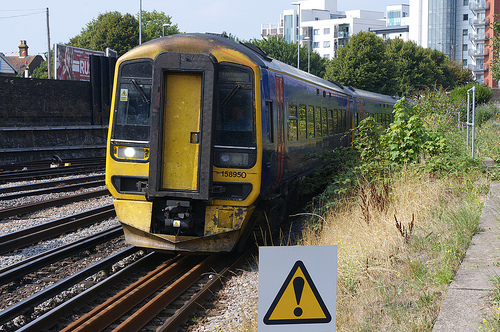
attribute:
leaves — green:
[144, 10, 172, 27]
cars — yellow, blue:
[90, 26, 402, 241]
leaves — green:
[338, 33, 466, 79]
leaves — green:
[314, 40, 476, 83]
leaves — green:
[362, 114, 484, 191]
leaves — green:
[330, 40, 436, 89]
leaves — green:
[261, 28, 435, 92]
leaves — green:
[251, 20, 341, 71]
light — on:
[120, 141, 148, 179]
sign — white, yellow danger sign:
[254, 242, 357, 329]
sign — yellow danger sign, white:
[256, 240, 344, 330]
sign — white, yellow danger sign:
[249, 238, 344, 329]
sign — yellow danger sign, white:
[249, 235, 352, 329]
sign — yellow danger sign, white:
[254, 229, 352, 329]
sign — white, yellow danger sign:
[242, 240, 342, 329]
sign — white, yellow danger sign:
[242, 245, 357, 327]